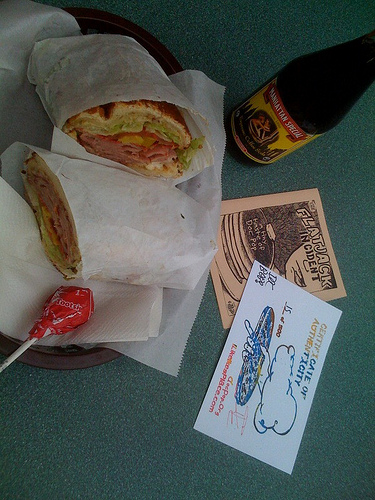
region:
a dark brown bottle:
[219, 28, 373, 168]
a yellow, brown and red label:
[230, 76, 320, 166]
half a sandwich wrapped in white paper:
[24, 28, 215, 190]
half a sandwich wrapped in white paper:
[1, 136, 214, 299]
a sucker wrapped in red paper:
[1, 284, 95, 378]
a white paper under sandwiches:
[0, 0, 226, 379]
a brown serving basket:
[0, 5, 199, 371]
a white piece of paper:
[191, 258, 343, 477]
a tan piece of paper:
[201, 186, 347, 327]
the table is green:
[0, 0, 373, 498]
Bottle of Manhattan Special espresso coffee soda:
[231, 23, 370, 164]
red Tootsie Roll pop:
[4, 284, 87, 379]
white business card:
[193, 265, 344, 475]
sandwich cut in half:
[17, 33, 215, 282]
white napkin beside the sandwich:
[2, 182, 162, 338]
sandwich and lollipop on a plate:
[2, 12, 217, 366]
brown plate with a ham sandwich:
[0, 6, 206, 367]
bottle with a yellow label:
[233, 31, 371, 162]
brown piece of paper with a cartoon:
[210, 187, 348, 327]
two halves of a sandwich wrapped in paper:
[25, 32, 215, 284]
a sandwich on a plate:
[24, 24, 254, 319]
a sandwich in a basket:
[29, 16, 258, 366]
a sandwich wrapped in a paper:
[25, 23, 266, 332]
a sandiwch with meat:
[11, 11, 241, 323]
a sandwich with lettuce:
[9, 12, 252, 324]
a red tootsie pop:
[7, 261, 157, 404]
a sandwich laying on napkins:
[8, 123, 311, 414]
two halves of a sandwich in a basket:
[16, 10, 294, 378]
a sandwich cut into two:
[10, 9, 292, 336]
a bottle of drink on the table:
[210, 14, 374, 236]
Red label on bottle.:
[262, 84, 322, 164]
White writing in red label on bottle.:
[265, 83, 302, 155]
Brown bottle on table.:
[268, 16, 329, 169]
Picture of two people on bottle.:
[248, 104, 272, 153]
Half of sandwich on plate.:
[16, 148, 77, 276]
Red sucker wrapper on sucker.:
[31, 281, 85, 342]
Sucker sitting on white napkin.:
[26, 275, 127, 340]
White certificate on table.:
[239, 273, 312, 435]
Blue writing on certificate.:
[292, 350, 318, 410]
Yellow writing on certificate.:
[299, 319, 335, 357]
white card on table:
[217, 239, 352, 474]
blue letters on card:
[284, 349, 324, 403]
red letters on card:
[196, 329, 261, 453]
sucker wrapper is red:
[21, 277, 137, 363]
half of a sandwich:
[51, 40, 225, 213]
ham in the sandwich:
[89, 127, 178, 168]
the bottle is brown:
[228, 45, 346, 180]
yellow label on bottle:
[238, 85, 339, 194]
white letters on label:
[259, 85, 309, 149]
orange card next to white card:
[225, 170, 374, 312]